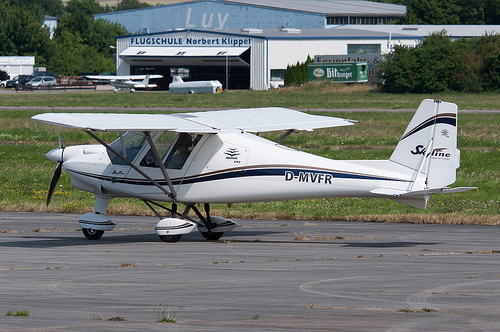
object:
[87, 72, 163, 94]
plane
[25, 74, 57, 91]
car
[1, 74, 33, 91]
car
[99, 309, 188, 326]
grass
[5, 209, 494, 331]
pavement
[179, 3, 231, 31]
word "luv"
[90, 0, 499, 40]
building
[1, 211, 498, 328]
runway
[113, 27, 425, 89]
building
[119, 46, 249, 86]
door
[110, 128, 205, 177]
cockpit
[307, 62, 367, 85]
green trailer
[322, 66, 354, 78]
lettering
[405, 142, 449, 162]
skyline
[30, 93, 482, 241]
model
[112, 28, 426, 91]
airplane hanger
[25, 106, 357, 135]
wings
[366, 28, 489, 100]
dark sky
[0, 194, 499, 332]
ground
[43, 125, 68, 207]
propeller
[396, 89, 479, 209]
fins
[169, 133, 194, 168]
guy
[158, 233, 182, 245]
wheel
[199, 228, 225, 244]
wheel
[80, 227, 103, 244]
wheel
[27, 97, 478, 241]
aircraft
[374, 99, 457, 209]
tail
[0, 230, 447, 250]
shadow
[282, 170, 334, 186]
writing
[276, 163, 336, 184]
identification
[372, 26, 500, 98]
bushes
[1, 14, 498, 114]
background